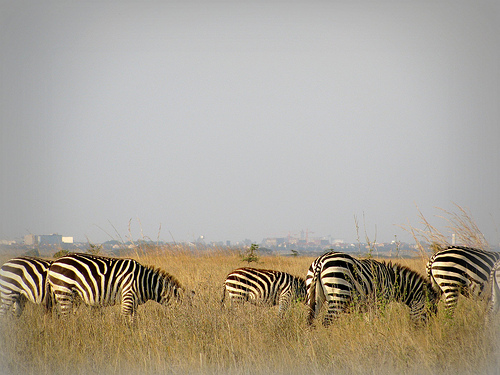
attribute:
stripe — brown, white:
[44, 261, 94, 307]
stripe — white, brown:
[43, 276, 79, 307]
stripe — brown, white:
[71, 250, 100, 292]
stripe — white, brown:
[104, 258, 129, 309]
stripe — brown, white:
[115, 258, 136, 300]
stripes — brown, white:
[302, 250, 437, 333]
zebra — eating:
[44, 249, 175, 331]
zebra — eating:
[35, 247, 200, 328]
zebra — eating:
[0, 252, 57, 320]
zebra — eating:
[210, 253, 303, 333]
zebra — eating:
[288, 229, 435, 325]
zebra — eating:
[409, 232, 497, 330]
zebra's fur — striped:
[304, 250, 437, 329]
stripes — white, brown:
[205, 228, 306, 340]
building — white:
[17, 231, 89, 244]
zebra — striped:
[213, 257, 312, 317]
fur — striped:
[317, 245, 424, 327]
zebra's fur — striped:
[401, 222, 499, 317]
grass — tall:
[1, 200, 498, 372]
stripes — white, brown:
[224, 266, 304, 308]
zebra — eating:
[0, 255, 53, 315]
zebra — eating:
[40, 252, 196, 319]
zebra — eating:
[220, 265, 310, 315]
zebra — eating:
[305, 250, 432, 328]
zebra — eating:
[425, 243, 484, 316]